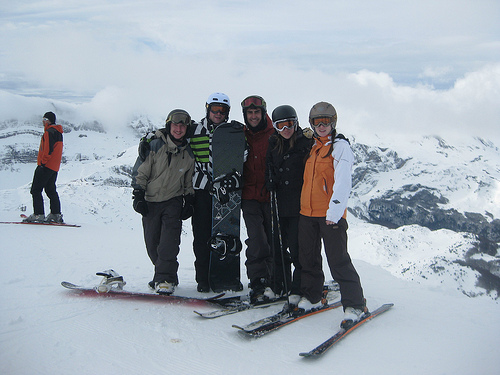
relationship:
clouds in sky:
[53, 52, 168, 109] [82, 124, 128, 148]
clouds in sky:
[2, 2, 499, 142] [1, 0, 499, 101]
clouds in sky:
[2, 2, 499, 142] [0, 2, 499, 135]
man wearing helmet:
[190, 94, 244, 294] [204, 90, 231, 115]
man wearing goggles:
[190, 94, 244, 294] [206, 103, 231, 116]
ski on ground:
[230, 300, 342, 335] [0, 225, 499, 374]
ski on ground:
[299, 301, 394, 361] [0, 225, 499, 374]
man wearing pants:
[130, 108, 195, 295] [142, 196, 182, 286]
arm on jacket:
[323, 138, 355, 222] [298, 132, 354, 221]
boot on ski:
[294, 296, 326, 316] [232, 297, 341, 338]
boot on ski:
[338, 305, 368, 329] [299, 301, 394, 361]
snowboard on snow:
[62, 266, 242, 304] [0, 223, 499, 373]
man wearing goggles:
[130, 108, 195, 295] [163, 109, 193, 125]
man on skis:
[28, 110, 63, 220] [4, 214, 83, 228]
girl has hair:
[261, 106, 312, 304] [273, 134, 301, 149]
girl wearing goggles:
[261, 106, 312, 304] [270, 116, 295, 131]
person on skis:
[295, 102, 369, 326] [230, 300, 393, 360]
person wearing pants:
[295, 102, 369, 326] [298, 216, 366, 307]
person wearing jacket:
[295, 102, 369, 326] [298, 132, 354, 221]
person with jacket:
[295, 102, 369, 326] [302, 140, 361, 225]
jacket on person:
[302, 140, 361, 225] [295, 102, 369, 326]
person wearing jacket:
[295, 102, 369, 326] [302, 140, 361, 225]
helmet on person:
[301, 93, 341, 124] [295, 102, 369, 326]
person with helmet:
[295, 102, 369, 326] [301, 93, 341, 124]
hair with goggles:
[273, 111, 300, 124] [270, 116, 295, 131]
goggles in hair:
[270, 116, 295, 131] [273, 111, 300, 124]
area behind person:
[93, 30, 433, 94] [295, 102, 369, 326]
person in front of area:
[295, 102, 369, 326] [93, 30, 433, 94]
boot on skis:
[294, 296, 326, 316] [228, 313, 394, 358]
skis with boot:
[228, 313, 394, 358] [294, 296, 326, 316]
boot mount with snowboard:
[81, 265, 132, 292] [62, 266, 242, 304]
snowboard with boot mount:
[62, 266, 242, 304] [81, 265, 132, 292]